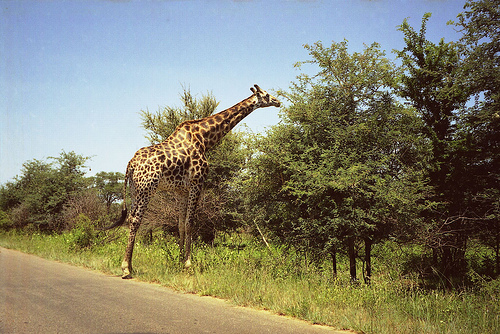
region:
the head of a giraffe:
[243, 55, 293, 122]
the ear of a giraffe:
[241, 73, 279, 121]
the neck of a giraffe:
[202, 92, 257, 148]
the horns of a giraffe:
[238, 73, 271, 108]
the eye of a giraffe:
[253, 88, 272, 109]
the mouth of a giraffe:
[274, 90, 294, 117]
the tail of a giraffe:
[117, 150, 142, 242]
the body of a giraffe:
[103, 118, 223, 280]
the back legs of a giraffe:
[108, 189, 174, 290]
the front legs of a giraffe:
[166, 145, 253, 263]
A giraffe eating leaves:
[112, 76, 287, 281]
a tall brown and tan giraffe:
[115, 84, 283, 278]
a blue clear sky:
[0, 0, 494, 190]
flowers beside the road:
[0, 229, 255, 273]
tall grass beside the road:
[0, 225, 497, 329]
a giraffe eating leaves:
[120, 79, 294, 279]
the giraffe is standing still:
[121, 81, 283, 283]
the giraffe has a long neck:
[118, 81, 281, 277]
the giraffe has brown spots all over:
[118, 81, 278, 278]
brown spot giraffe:
[184, 122, 191, 132]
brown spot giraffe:
[193, 130, 202, 140]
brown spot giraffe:
[198, 142, 205, 156]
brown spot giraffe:
[185, 127, 193, 143]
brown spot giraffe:
[166, 139, 173, 146]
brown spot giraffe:
[171, 147, 178, 154]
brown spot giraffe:
[148, 146, 156, 153]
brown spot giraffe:
[156, 155, 165, 163]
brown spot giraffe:
[138, 164, 145, 169]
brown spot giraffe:
[171, 163, 182, 174]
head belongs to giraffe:
[246, 84, 280, 111]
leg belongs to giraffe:
[182, 173, 197, 265]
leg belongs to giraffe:
[173, 187, 185, 267]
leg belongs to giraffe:
[123, 183, 155, 276]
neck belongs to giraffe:
[197, 93, 257, 150]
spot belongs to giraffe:
[187, 123, 201, 133]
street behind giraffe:
[1, 243, 358, 333]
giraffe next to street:
[117, 85, 287, 279]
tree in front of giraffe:
[254, 39, 414, 279]